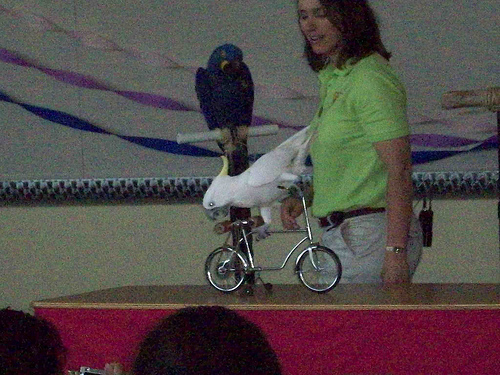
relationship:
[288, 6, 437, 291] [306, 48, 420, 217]
woman in polo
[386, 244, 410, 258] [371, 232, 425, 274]
watch on wrist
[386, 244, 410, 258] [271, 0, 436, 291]
watch on woman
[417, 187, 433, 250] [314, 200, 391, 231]
walkie talkie on belt